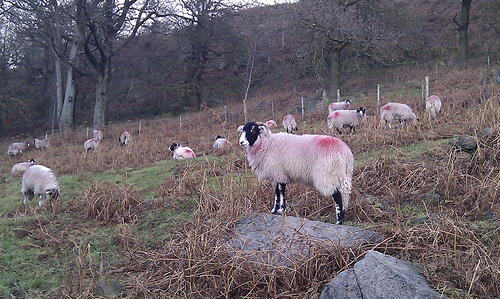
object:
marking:
[315, 134, 338, 152]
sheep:
[237, 121, 354, 224]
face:
[237, 122, 258, 147]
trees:
[452, 0, 473, 60]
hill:
[2, 0, 498, 298]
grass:
[0, 52, 500, 299]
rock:
[214, 212, 382, 284]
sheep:
[168, 142, 194, 161]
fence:
[0, 54, 496, 146]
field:
[0, 65, 499, 298]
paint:
[185, 149, 192, 155]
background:
[1, 0, 498, 298]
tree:
[0, 0, 191, 140]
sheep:
[20, 165, 60, 215]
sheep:
[378, 101, 421, 131]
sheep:
[424, 95, 441, 117]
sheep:
[119, 131, 129, 146]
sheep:
[83, 130, 103, 152]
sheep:
[7, 141, 30, 158]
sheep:
[327, 100, 351, 115]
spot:
[332, 113, 338, 119]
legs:
[332, 190, 345, 228]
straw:
[0, 69, 500, 298]